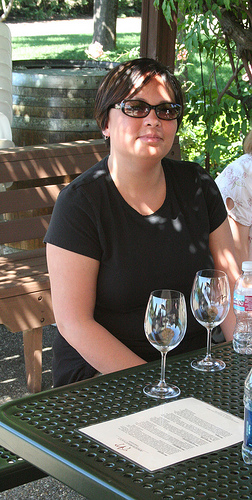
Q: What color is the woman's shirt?
A: Black.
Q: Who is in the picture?
A: A woman.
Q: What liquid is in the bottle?
A: Water.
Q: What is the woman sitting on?
A: A bench.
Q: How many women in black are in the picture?
A: One.